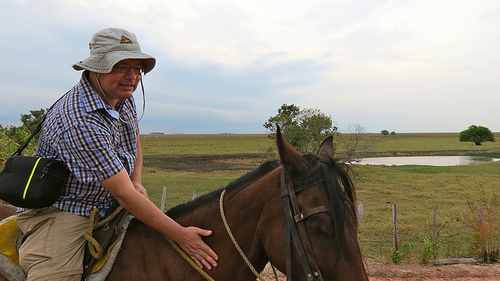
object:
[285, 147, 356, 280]
harness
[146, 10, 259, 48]
cloud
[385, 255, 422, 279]
dirt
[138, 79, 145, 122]
strap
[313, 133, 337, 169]
ears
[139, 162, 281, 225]
mane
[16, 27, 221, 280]
man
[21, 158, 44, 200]
stripe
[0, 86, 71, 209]
bag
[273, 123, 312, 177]
ears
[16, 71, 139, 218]
plaid shirt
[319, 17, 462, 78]
clouds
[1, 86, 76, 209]
bag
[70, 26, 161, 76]
hat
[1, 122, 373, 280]
horse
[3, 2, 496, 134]
sky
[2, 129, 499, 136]
horizon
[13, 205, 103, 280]
cargo pants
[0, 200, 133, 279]
saddle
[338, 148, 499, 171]
pond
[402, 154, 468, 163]
water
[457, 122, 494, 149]
tree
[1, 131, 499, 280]
field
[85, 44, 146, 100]
head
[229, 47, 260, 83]
part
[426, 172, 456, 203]
part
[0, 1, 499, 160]
background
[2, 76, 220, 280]
body